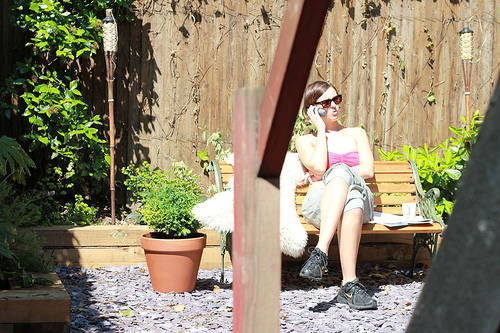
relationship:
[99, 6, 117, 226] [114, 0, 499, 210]
torch near fence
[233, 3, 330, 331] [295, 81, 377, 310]
red column near she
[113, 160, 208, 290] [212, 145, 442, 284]
plant near bench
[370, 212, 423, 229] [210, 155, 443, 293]
paper on bench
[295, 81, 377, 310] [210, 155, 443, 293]
she on bench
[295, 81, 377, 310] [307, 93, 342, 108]
she wears sunglasses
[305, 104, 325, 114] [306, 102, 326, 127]
phone in hand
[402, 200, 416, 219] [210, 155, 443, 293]
cup on bench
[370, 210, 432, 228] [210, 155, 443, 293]
paper on bench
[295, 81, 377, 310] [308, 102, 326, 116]
she on phone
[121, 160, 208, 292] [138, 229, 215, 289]
plant in pot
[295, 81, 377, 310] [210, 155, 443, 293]
she sitting on bench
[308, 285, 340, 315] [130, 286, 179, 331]
shadows on ground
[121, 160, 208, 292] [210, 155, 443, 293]
plant by bench